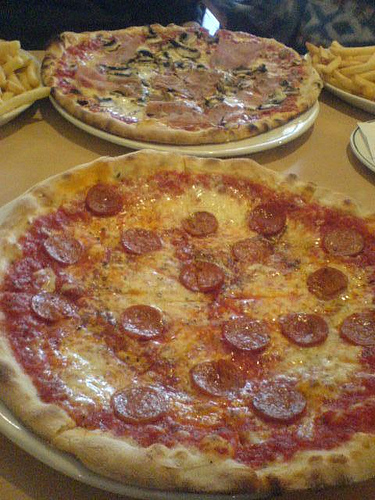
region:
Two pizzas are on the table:
[5, 24, 367, 489]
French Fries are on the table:
[290, 30, 372, 127]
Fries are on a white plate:
[300, 30, 371, 113]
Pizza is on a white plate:
[0, 352, 328, 496]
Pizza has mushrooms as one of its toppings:
[80, 30, 267, 128]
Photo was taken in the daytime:
[8, 0, 356, 334]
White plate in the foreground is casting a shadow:
[0, 416, 202, 493]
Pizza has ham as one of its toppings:
[81, 34, 276, 124]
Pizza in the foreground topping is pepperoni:
[53, 191, 342, 411]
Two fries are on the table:
[0, 26, 372, 129]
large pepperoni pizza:
[0, 146, 374, 499]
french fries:
[0, 41, 50, 119]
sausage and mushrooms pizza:
[40, 20, 322, 157]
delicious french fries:
[301, 39, 373, 107]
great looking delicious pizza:
[0, 145, 371, 497]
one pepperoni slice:
[120, 301, 166, 338]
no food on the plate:
[350, 117, 372, 171]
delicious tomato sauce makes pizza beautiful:
[4, 226, 79, 373]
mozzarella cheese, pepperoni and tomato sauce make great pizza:
[38, 215, 343, 410]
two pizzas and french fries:
[0, 20, 371, 499]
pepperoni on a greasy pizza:
[124, 210, 236, 286]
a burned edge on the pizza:
[242, 472, 277, 489]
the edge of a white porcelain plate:
[21, 438, 43, 453]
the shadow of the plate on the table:
[5, 463, 43, 494]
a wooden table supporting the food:
[13, 126, 61, 168]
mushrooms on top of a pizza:
[134, 38, 206, 67]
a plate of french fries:
[321, 33, 371, 89]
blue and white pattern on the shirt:
[321, 3, 357, 34]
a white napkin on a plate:
[352, 121, 372, 155]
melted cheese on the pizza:
[132, 205, 173, 224]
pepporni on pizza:
[39, 211, 294, 409]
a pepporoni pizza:
[22, 159, 336, 487]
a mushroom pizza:
[66, 30, 324, 147]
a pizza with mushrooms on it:
[117, 45, 263, 132]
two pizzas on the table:
[44, 18, 341, 477]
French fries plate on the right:
[301, 44, 373, 112]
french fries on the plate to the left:
[0, 32, 44, 120]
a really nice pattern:
[269, 7, 374, 31]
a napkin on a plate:
[347, 115, 372, 141]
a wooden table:
[303, 128, 358, 184]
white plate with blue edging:
[337, 101, 373, 177]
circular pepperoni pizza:
[1, 240, 372, 491]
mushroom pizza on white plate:
[38, 15, 324, 152]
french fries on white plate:
[305, 16, 369, 103]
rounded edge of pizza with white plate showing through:
[240, 111, 303, 152]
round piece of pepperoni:
[279, 301, 339, 353]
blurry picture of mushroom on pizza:
[169, 39, 203, 61]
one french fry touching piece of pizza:
[10, 74, 88, 118]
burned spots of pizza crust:
[239, 109, 288, 136]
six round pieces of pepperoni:
[105, 290, 331, 429]